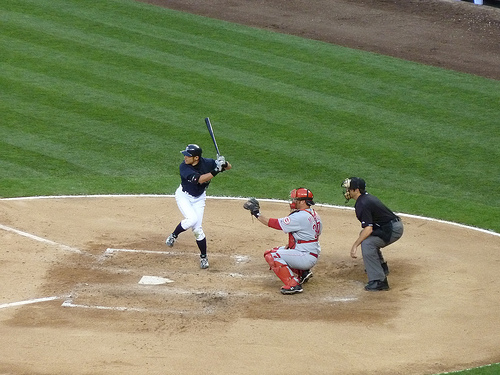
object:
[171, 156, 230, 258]
uniform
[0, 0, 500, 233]
grass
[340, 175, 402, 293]
umpire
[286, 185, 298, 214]
catchers mask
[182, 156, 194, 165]
face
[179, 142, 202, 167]
head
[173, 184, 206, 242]
pants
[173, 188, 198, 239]
leg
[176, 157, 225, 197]
shirt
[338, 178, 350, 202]
mask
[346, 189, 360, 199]
face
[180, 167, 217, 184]
arm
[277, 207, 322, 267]
gray uniform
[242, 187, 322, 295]
catcher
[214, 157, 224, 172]
hand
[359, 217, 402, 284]
pants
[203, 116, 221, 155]
bat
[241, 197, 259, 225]
mitt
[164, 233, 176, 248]
foot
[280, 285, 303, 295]
foot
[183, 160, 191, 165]
chin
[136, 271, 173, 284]
plate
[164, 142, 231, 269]
man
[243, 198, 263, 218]
hand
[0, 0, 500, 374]
baseball field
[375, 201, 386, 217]
black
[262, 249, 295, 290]
shin guard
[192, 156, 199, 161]
ear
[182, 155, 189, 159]
nose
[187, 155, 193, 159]
eye